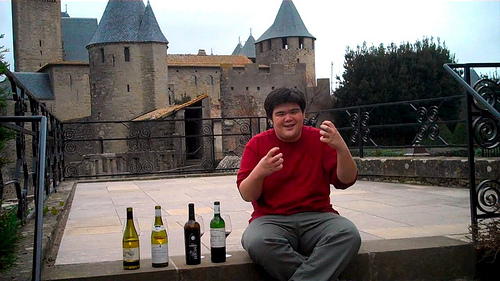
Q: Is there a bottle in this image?
A: Yes, there is a bottle.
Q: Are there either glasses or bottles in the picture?
A: Yes, there is a bottle.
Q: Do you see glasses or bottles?
A: Yes, there is a bottle.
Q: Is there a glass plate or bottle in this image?
A: Yes, there is a glass bottle.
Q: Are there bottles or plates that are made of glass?
A: Yes, the bottle is made of glass.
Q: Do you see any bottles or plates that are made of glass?
A: Yes, the bottle is made of glass.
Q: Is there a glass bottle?
A: Yes, there is a bottle that is made of glass.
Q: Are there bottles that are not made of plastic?
A: Yes, there is a bottle that is made of glass.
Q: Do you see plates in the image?
A: No, there are no plates.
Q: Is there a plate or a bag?
A: No, there are no plates or bags.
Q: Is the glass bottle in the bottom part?
A: Yes, the bottle is in the bottom of the image.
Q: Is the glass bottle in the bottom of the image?
A: Yes, the bottle is in the bottom of the image.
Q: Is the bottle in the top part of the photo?
A: No, the bottle is in the bottom of the image.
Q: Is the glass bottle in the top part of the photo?
A: No, the bottle is in the bottom of the image.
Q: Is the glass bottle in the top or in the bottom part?
A: The bottle is in the bottom of the image.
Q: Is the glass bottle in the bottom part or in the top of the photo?
A: The bottle is in the bottom of the image.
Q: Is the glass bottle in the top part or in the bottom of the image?
A: The bottle is in the bottom of the image.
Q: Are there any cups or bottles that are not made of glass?
A: No, there is a bottle but it is made of glass.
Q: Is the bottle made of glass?
A: Yes, the bottle is made of glass.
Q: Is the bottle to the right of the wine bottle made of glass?
A: Yes, the bottle is made of glass.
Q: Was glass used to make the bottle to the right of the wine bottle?
A: Yes, the bottle is made of glass.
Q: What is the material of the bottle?
A: The bottle is made of glass.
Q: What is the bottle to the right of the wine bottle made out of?
A: The bottle is made of glass.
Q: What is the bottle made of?
A: The bottle is made of glass.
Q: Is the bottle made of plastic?
A: No, the bottle is made of glass.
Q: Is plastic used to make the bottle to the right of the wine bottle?
A: No, the bottle is made of glass.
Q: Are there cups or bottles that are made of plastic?
A: No, there is a bottle but it is made of glass.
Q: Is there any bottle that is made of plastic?
A: No, there is a bottle but it is made of glass.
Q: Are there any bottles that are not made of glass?
A: No, there is a bottle but it is made of glass.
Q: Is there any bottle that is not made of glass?
A: No, there is a bottle but it is made of glass.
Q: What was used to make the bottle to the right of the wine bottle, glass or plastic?
A: The bottle is made of glass.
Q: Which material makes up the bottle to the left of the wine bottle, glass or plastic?
A: The bottle is made of glass.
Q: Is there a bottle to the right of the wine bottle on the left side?
A: Yes, there is a bottle to the right of the wine bottle.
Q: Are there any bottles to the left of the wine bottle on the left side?
A: No, the bottle is to the right of the wine bottle.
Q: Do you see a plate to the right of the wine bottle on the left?
A: No, there is a bottle to the right of the wine bottle.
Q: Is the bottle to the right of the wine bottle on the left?
A: Yes, the bottle is to the right of the wine bottle.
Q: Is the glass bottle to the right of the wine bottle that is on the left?
A: Yes, the bottle is to the right of the wine bottle.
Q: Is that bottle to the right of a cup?
A: No, the bottle is to the right of the wine bottle.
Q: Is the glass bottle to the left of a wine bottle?
A: No, the bottle is to the right of a wine bottle.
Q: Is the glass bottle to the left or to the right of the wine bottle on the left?
A: The bottle is to the right of the wine bottle.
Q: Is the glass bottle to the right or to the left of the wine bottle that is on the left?
A: The bottle is to the right of the wine bottle.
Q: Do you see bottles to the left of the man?
A: Yes, there is a bottle to the left of the man.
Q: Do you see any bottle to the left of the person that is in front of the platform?
A: Yes, there is a bottle to the left of the man.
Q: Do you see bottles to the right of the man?
A: No, the bottle is to the left of the man.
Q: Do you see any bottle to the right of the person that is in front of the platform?
A: No, the bottle is to the left of the man.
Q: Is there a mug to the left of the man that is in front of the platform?
A: No, there is a bottle to the left of the man.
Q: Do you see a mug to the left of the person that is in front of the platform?
A: No, there is a bottle to the left of the man.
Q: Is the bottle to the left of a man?
A: Yes, the bottle is to the left of a man.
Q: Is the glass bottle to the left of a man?
A: Yes, the bottle is to the left of a man.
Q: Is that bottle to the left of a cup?
A: No, the bottle is to the left of a man.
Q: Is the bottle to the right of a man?
A: No, the bottle is to the left of a man.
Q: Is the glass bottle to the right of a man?
A: No, the bottle is to the left of a man.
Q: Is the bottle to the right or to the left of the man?
A: The bottle is to the left of the man.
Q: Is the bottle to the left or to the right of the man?
A: The bottle is to the left of the man.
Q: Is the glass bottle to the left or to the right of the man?
A: The bottle is to the left of the man.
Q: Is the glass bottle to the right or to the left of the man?
A: The bottle is to the left of the man.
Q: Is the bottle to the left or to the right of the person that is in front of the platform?
A: The bottle is to the left of the man.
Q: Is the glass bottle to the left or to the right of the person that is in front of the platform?
A: The bottle is to the left of the man.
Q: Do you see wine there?
A: Yes, there is wine.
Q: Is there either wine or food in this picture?
A: Yes, there is wine.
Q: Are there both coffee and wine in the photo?
A: No, there is wine but no coffee.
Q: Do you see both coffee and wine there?
A: No, there is wine but no coffee.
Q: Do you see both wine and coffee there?
A: No, there is wine but no coffee.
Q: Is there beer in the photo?
A: No, there is no beer.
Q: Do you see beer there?
A: No, there is no beer.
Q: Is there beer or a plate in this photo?
A: No, there are no beer or plates.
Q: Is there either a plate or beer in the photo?
A: No, there are no beer or plates.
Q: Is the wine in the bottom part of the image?
A: Yes, the wine is in the bottom of the image.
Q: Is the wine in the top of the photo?
A: No, the wine is in the bottom of the image.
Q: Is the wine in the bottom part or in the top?
A: The wine is in the bottom of the image.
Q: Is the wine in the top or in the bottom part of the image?
A: The wine is in the bottom of the image.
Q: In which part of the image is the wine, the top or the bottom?
A: The wine is in the bottom of the image.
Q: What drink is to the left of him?
A: The drink is wine.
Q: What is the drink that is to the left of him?
A: The drink is wine.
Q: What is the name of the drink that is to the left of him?
A: The drink is wine.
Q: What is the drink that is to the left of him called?
A: The drink is wine.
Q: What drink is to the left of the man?
A: The drink is wine.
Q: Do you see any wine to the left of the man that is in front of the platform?
A: Yes, there is wine to the left of the man.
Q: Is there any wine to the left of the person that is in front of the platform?
A: Yes, there is wine to the left of the man.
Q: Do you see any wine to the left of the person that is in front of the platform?
A: Yes, there is wine to the left of the man.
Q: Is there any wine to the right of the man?
A: No, the wine is to the left of the man.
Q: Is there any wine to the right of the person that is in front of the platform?
A: No, the wine is to the left of the man.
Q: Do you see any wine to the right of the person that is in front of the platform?
A: No, the wine is to the left of the man.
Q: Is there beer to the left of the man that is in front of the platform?
A: No, there is wine to the left of the man.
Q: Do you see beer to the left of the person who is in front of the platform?
A: No, there is wine to the left of the man.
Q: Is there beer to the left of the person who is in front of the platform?
A: No, there is wine to the left of the man.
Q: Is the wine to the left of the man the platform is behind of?
A: Yes, the wine is to the left of the man.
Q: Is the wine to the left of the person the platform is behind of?
A: Yes, the wine is to the left of the man.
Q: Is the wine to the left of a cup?
A: No, the wine is to the left of the man.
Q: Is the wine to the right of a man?
A: No, the wine is to the left of a man.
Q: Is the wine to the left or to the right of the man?
A: The wine is to the left of the man.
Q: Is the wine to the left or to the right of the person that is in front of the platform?
A: The wine is to the left of the man.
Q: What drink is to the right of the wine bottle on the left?
A: The drink is wine.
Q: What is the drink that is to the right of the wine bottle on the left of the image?
A: The drink is wine.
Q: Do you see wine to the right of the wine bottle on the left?
A: Yes, there is wine to the right of the wine bottle.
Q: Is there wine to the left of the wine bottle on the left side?
A: No, the wine is to the right of the wine bottle.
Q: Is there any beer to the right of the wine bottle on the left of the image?
A: No, there is wine to the right of the wine bottle.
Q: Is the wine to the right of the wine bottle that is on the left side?
A: Yes, the wine is to the right of the wine bottle.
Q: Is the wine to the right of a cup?
A: No, the wine is to the right of the wine bottle.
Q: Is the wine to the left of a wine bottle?
A: No, the wine is to the right of a wine bottle.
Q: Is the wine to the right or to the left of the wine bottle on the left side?
A: The wine is to the right of the wine bottle.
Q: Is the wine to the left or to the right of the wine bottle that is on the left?
A: The wine is to the right of the wine bottle.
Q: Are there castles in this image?
A: Yes, there is a castle.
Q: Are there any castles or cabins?
A: Yes, there is a castle.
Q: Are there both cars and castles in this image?
A: No, there is a castle but no cars.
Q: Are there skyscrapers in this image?
A: No, there are no skyscrapers.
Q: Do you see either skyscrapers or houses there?
A: No, there are no skyscrapers or houses.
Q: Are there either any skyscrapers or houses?
A: No, there are no skyscrapers or houses.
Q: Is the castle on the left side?
A: Yes, the castle is on the left of the image.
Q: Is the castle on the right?
A: No, the castle is on the left of the image.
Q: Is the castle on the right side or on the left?
A: The castle is on the left of the image.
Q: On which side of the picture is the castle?
A: The castle is on the left of the image.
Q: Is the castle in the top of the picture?
A: Yes, the castle is in the top of the image.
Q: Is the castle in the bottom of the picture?
A: No, the castle is in the top of the image.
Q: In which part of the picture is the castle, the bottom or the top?
A: The castle is in the top of the image.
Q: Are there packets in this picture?
A: No, there are no packets.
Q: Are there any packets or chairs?
A: No, there are no packets or chairs.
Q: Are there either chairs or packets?
A: No, there are no packets or chairs.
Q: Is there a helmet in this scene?
A: No, there are no helmets.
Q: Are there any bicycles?
A: No, there are no bicycles.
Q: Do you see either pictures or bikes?
A: No, there are no bikes or pictures.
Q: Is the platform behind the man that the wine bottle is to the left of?
A: Yes, the platform is behind the man.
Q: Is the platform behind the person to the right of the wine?
A: Yes, the platform is behind the man.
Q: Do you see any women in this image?
A: No, there are no women.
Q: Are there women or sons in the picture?
A: No, there are no women or sons.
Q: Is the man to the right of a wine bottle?
A: Yes, the man is to the right of a wine bottle.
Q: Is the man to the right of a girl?
A: No, the man is to the right of a wine bottle.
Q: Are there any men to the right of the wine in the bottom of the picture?
A: Yes, there is a man to the right of the wine.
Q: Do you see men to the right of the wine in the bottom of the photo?
A: Yes, there is a man to the right of the wine.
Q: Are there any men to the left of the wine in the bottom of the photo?
A: No, the man is to the right of the wine.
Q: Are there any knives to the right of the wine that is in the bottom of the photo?
A: No, there is a man to the right of the wine.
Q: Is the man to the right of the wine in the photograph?
A: Yes, the man is to the right of the wine.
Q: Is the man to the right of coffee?
A: No, the man is to the right of the wine.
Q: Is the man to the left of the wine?
A: No, the man is to the right of the wine.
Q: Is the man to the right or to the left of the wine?
A: The man is to the right of the wine.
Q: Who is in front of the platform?
A: The man is in front of the platform.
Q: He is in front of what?
A: The man is in front of the platform.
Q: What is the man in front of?
A: The man is in front of the platform.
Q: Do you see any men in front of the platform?
A: Yes, there is a man in front of the platform.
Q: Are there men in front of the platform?
A: Yes, there is a man in front of the platform.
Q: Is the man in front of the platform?
A: Yes, the man is in front of the platform.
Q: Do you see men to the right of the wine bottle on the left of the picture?
A: Yes, there is a man to the right of the wine bottle.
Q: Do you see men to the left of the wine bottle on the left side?
A: No, the man is to the right of the wine bottle.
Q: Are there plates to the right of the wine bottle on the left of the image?
A: No, there is a man to the right of the wine bottle.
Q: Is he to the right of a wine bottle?
A: Yes, the man is to the right of a wine bottle.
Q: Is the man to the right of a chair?
A: No, the man is to the right of a wine bottle.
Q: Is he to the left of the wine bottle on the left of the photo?
A: No, the man is to the right of the wine bottle.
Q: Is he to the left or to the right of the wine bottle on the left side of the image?
A: The man is to the right of the wine bottle.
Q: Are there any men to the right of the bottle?
A: Yes, there is a man to the right of the bottle.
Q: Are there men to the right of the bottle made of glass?
A: Yes, there is a man to the right of the bottle.